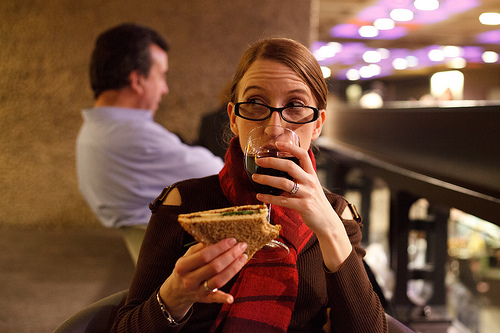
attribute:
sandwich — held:
[178, 200, 285, 265]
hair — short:
[88, 20, 169, 97]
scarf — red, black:
[243, 268, 295, 318]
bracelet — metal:
[156, 286, 181, 326]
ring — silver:
[290, 182, 299, 194]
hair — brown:
[224, 34, 326, 109]